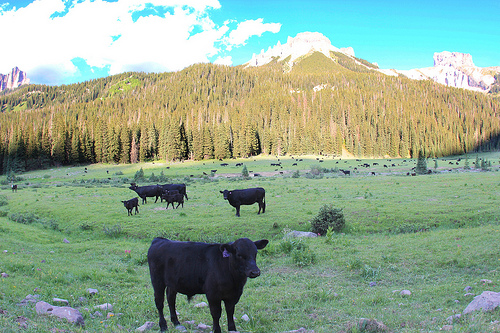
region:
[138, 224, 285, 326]
black cow in the field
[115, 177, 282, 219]
group of black cows in the field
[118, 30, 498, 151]
mountains in the distance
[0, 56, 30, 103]
mountains in the distance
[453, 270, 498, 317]
rock in the field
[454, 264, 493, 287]
rock in the field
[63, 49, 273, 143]
buoy in the lake water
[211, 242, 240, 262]
black ears on cow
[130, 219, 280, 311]
black cow in the field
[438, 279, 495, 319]
large stones in the field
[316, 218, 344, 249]
small cluster of green trees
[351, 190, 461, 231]
green grass on the meadow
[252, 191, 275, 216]
long tail on the cow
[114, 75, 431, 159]
forest of tall green trees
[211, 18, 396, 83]
tall mountain range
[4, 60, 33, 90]
tall rock cluster in the distance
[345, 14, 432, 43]
vibrant blue skies overhead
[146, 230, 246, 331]
Black cow in a field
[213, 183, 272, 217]
Black cow in a field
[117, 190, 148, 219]
Black cow in a field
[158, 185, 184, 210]
Black cow in a field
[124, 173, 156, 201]
Black cow in a field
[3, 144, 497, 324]
Group of cows in a field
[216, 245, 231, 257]
purple tag in cow ear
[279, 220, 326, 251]
large rock on the ground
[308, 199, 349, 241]
Bush in the field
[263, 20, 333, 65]
snow on a mountain top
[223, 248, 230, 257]
The tag in the cow's ear.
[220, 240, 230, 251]
The left ear of the cow in the front.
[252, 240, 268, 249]
The right ear of the cow in the front.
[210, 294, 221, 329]
The front left leg of the cow in the front.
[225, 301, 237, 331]
The front right leg of the cow in the front.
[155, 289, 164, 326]
The back left leg of the cow in the front.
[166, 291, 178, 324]
The back right leg of the cow in the front.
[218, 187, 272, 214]
The cow in the middle.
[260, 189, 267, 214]
The tail of the cow in the middle.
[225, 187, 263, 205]
The body of the cow in the middle.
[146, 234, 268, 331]
the black cattle is standing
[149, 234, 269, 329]
blue color tag in the ear of cattle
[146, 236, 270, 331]
blue color tag in left ear of the cattle